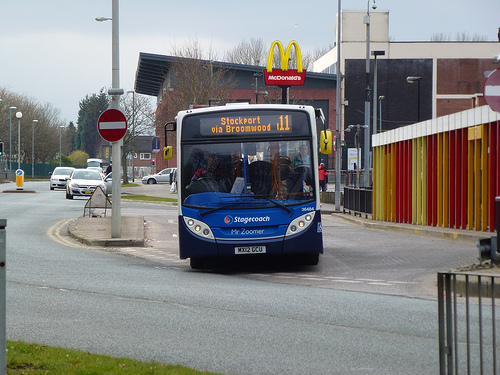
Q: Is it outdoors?
A: Yes, it is outdoors.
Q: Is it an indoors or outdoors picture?
A: It is outdoors.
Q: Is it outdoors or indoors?
A: It is outdoors.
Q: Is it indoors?
A: No, it is outdoors.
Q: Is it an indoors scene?
A: No, it is outdoors.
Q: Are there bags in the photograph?
A: No, there are no bags.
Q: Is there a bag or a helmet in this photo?
A: No, there are no bags or helmets.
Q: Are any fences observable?
A: Yes, there is a fence.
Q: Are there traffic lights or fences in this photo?
A: Yes, there is a fence.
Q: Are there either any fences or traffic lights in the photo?
A: Yes, there is a fence.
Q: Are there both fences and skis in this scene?
A: No, there is a fence but no skis.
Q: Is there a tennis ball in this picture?
A: No, there are no tennis balls.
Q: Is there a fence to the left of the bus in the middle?
A: Yes, there is a fence to the left of the bus.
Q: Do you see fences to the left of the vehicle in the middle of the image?
A: Yes, there is a fence to the left of the bus.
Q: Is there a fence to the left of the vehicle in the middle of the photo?
A: Yes, there is a fence to the left of the bus.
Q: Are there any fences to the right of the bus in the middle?
A: No, the fence is to the left of the bus.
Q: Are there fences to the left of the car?
A: Yes, there is a fence to the left of the car.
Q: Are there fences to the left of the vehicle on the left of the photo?
A: Yes, there is a fence to the left of the car.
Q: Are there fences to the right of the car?
A: No, the fence is to the left of the car.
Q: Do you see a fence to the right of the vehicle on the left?
A: No, the fence is to the left of the car.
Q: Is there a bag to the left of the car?
A: No, there is a fence to the left of the car.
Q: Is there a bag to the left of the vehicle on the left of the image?
A: No, there is a fence to the left of the car.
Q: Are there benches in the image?
A: No, there are no benches.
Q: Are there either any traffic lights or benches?
A: No, there are no benches or traffic lights.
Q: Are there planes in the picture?
A: No, there are no planes.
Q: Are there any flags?
A: No, there are no flags.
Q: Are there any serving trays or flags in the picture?
A: No, there are no flags or serving trays.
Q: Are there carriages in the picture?
A: No, there are no carriages.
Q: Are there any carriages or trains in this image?
A: No, there are no carriages or trains.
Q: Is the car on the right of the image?
A: No, the car is on the left of the image.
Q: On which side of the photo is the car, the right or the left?
A: The car is on the left of the image.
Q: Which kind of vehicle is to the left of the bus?
A: The vehicle is a car.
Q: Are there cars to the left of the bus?
A: Yes, there is a car to the left of the bus.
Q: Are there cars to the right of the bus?
A: No, the car is to the left of the bus.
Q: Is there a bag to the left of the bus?
A: No, there is a car to the left of the bus.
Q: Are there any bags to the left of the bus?
A: No, there is a car to the left of the bus.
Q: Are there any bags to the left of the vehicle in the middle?
A: No, there is a car to the left of the bus.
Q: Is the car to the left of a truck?
A: No, the car is to the left of the bus.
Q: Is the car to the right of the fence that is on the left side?
A: Yes, the car is to the right of the fence.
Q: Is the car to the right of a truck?
A: No, the car is to the right of the fence.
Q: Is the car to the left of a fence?
A: No, the car is to the right of a fence.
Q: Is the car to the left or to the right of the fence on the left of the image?
A: The car is to the right of the fence.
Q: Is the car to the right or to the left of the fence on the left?
A: The car is to the right of the fence.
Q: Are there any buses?
A: Yes, there is a bus.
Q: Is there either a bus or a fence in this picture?
A: Yes, there is a bus.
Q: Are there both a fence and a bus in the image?
A: Yes, there are both a bus and a fence.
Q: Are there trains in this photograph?
A: No, there are no trains.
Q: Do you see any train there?
A: No, there are no trains.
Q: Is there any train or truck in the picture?
A: No, there are no trains or trucks.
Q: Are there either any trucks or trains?
A: No, there are no trains or trucks.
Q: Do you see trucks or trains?
A: No, there are no trains or trucks.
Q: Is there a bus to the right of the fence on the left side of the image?
A: Yes, there is a bus to the right of the fence.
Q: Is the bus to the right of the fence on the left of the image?
A: Yes, the bus is to the right of the fence.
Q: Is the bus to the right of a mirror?
A: No, the bus is to the right of the fence.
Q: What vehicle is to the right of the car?
A: The vehicle is a bus.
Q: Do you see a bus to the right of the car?
A: Yes, there is a bus to the right of the car.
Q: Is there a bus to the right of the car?
A: Yes, there is a bus to the right of the car.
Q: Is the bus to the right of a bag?
A: No, the bus is to the right of the car.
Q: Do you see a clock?
A: No, there are no clocks.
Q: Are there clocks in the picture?
A: No, there are no clocks.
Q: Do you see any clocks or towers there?
A: No, there are no clocks or towers.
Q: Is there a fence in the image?
A: Yes, there is a fence.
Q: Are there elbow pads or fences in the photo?
A: Yes, there is a fence.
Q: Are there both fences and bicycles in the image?
A: No, there is a fence but no bicycles.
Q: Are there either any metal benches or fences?
A: Yes, there is a metal fence.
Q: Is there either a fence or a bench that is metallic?
A: Yes, the fence is metallic.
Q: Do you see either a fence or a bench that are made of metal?
A: Yes, the fence is made of metal.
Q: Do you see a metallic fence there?
A: Yes, there is a metal fence.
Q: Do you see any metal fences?
A: Yes, there is a metal fence.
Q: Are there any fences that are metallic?
A: Yes, there is a fence that is metallic.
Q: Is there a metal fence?
A: Yes, there is a fence that is made of metal.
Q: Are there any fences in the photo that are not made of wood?
A: Yes, there is a fence that is made of metal.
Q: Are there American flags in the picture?
A: No, there are no American flags.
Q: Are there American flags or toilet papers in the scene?
A: No, there are no American flags or toilet papers.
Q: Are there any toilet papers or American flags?
A: No, there are no American flags or toilet papers.